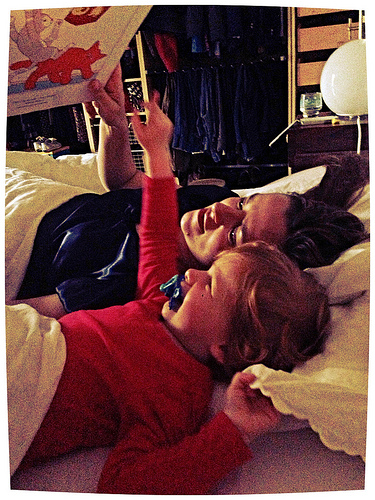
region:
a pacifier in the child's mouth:
[158, 271, 189, 310]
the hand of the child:
[221, 368, 283, 443]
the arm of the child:
[90, 369, 293, 492]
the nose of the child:
[184, 265, 205, 288]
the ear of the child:
[207, 341, 235, 362]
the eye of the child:
[203, 275, 216, 290]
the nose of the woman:
[210, 199, 233, 222]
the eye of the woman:
[235, 193, 247, 208]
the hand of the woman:
[82, 59, 126, 125]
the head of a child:
[158, 237, 333, 373]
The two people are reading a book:
[27, 33, 350, 384]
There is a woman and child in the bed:
[17, 48, 332, 372]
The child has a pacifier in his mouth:
[41, 204, 345, 477]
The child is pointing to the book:
[16, 56, 338, 405]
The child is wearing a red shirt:
[31, 237, 326, 465]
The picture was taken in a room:
[19, 16, 335, 473]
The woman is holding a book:
[13, 13, 322, 373]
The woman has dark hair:
[29, 102, 340, 368]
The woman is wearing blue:
[17, 102, 349, 377]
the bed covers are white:
[16, 102, 349, 375]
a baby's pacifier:
[156, 270, 192, 315]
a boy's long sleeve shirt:
[41, 298, 242, 488]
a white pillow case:
[233, 265, 371, 461]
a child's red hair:
[219, 246, 331, 372]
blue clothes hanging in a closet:
[145, 68, 296, 167]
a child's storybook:
[7, 1, 143, 124]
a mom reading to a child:
[21, 19, 318, 450]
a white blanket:
[0, 148, 95, 469]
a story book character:
[10, 40, 110, 92]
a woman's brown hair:
[284, 150, 369, 270]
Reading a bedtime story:
[10, 41, 148, 112]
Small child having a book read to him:
[75, 151, 320, 466]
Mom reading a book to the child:
[58, 146, 369, 246]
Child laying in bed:
[0, 358, 307, 469]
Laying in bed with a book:
[92, 166, 333, 361]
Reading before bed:
[44, 36, 355, 234]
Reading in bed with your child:
[21, 19, 207, 183]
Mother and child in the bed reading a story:
[14, 68, 327, 448]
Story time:
[0, 22, 269, 474]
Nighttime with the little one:
[43, 176, 340, 416]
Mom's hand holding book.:
[87, 57, 130, 142]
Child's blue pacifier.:
[155, 273, 186, 309]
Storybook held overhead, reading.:
[7, 5, 155, 116]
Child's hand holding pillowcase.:
[223, 370, 289, 438]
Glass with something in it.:
[297, 91, 325, 120]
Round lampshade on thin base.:
[320, 36, 367, 155]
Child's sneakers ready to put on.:
[31, 135, 64, 153]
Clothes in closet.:
[148, 6, 280, 160]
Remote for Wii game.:
[293, 113, 337, 129]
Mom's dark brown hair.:
[284, 153, 365, 268]